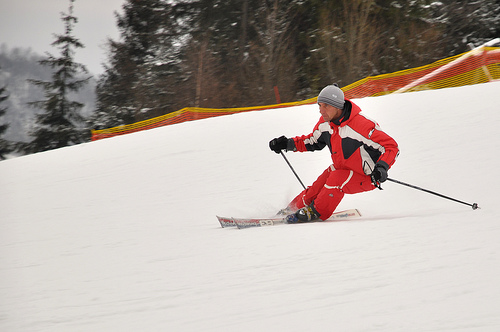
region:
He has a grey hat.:
[313, 80, 354, 115]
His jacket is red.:
[277, 115, 399, 165]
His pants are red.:
[284, 160, 369, 215]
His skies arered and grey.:
[206, 210, 371, 230]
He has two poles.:
[205, 84, 468, 244]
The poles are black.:
[215, 88, 481, 245]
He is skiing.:
[178, 70, 451, 237]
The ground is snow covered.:
[31, 131, 466, 328]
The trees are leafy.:
[10, 2, 474, 91]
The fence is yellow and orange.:
[73, 45, 498, 147]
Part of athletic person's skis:
[212, 203, 277, 233]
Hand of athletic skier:
[270, 135, 290, 150]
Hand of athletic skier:
[365, 165, 390, 182]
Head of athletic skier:
[315, 81, 347, 113]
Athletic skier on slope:
[271, 81, 397, 222]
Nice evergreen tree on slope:
[23, 0, 90, 150]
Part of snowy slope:
[47, 175, 139, 225]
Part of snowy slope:
[186, 258, 282, 310]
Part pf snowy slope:
[361, 240, 448, 304]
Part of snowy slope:
[422, 130, 478, 158]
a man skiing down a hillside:
[38, 31, 486, 251]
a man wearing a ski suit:
[221, 76, 401, 230]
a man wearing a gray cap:
[309, 80, 346, 130]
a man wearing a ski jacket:
[271, 80, 398, 186]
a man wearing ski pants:
[266, 78, 403, 221]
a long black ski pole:
[381, 169, 481, 217]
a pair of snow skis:
[210, 203, 365, 229]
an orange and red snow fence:
[90, 97, 269, 142]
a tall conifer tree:
[24, 0, 99, 155]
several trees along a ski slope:
[115, 0, 497, 82]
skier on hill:
[256, 72, 386, 237]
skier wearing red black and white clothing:
[236, 80, 392, 232]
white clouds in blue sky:
[5, 10, 40, 35]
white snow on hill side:
[70, 157, 121, 208]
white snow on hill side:
[146, 145, 181, 183]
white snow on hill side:
[27, 182, 84, 238]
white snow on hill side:
[25, 215, 85, 290]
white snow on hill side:
[125, 237, 210, 322]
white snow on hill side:
[210, 275, 258, 312]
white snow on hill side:
[258, 238, 330, 292]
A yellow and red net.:
[83, 37, 498, 142]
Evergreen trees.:
[0, 1, 497, 166]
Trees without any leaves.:
[157, 1, 468, 126]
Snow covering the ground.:
[0, 77, 498, 330]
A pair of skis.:
[214, 207, 361, 229]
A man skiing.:
[211, 80, 487, 230]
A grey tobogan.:
[318, 83, 347, 108]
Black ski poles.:
[272, 139, 482, 214]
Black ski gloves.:
[273, 137, 389, 180]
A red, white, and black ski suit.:
[282, 101, 405, 227]